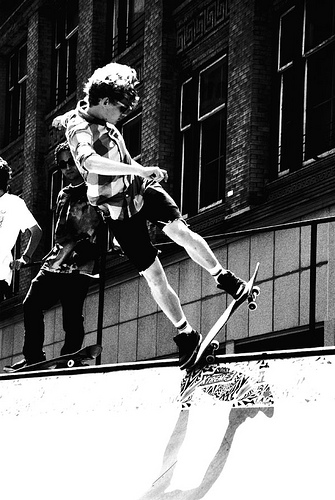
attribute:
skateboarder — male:
[53, 58, 268, 334]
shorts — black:
[98, 162, 199, 270]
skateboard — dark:
[4, 344, 102, 372]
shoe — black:
[206, 267, 251, 304]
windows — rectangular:
[173, 48, 232, 220]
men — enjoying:
[60, 49, 261, 318]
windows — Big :
[176, 51, 243, 220]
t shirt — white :
[1, 191, 37, 283]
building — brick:
[0, 10, 332, 281]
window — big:
[194, 49, 231, 212]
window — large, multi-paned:
[179, 52, 228, 220]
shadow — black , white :
[144, 360, 275, 497]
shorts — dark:
[112, 183, 182, 271]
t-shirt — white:
[1, 192, 34, 286]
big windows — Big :
[272, 2, 332, 180]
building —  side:
[2, 0, 334, 352]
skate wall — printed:
[1, 346, 333, 499]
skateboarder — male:
[4, 142, 103, 370]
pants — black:
[22, 268, 85, 364]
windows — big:
[182, 89, 189, 97]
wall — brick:
[8, 8, 332, 231]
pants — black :
[15, 269, 106, 381]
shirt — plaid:
[80, 135, 119, 204]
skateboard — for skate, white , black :
[184, 260, 261, 372]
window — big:
[175, 55, 229, 218]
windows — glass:
[136, 56, 243, 209]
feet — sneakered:
[166, 262, 249, 369]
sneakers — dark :
[168, 271, 247, 370]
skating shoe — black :
[168, 323, 201, 368]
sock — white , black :
[170, 312, 197, 337]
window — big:
[266, 1, 334, 178]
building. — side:
[2, 5, 324, 355]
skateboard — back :
[204, 340, 219, 364]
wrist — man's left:
[116, 164, 159, 184]